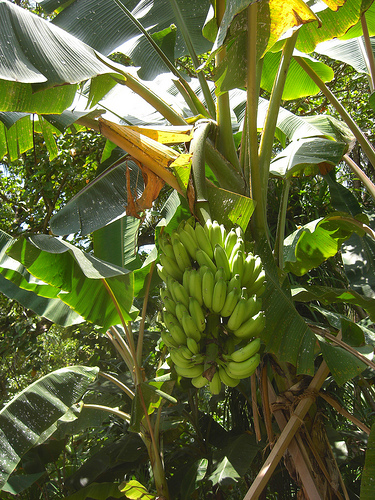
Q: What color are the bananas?
A: Green.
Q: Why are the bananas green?
A: They are not ripe yet.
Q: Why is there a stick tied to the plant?
A: To keep the plant from falling over.